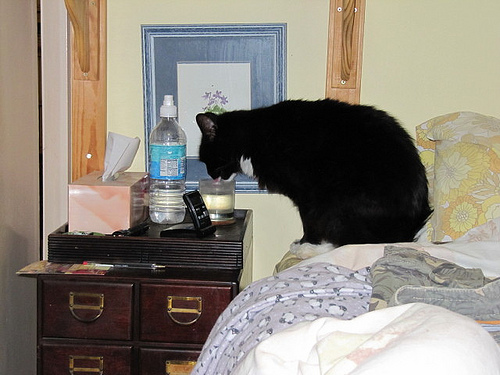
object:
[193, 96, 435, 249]
cat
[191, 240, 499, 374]
bed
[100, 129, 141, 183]
tissue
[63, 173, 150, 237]
box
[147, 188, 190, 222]
water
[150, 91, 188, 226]
bottle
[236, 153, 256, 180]
patch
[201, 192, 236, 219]
water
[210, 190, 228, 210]
glass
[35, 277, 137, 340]
drawer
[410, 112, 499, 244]
pillowcase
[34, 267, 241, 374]
table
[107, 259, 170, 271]
pen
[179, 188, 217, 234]
clock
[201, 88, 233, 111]
flower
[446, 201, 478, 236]
flowers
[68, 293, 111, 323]
pull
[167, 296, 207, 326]
pull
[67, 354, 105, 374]
pull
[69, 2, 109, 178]
bracket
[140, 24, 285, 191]
frame